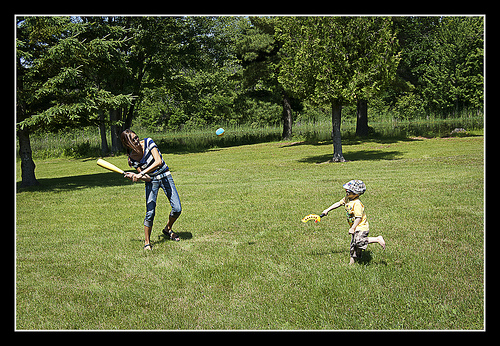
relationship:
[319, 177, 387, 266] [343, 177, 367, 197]
kid wearing hat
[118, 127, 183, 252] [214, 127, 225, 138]
woman hitting ball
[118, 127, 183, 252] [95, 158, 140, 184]
woman holding bat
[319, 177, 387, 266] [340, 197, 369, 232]
kid wearing shirt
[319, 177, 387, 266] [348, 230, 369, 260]
kid wearing shorts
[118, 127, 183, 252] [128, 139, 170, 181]
woman wearing shirt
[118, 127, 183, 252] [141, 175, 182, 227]
woman wearing jeans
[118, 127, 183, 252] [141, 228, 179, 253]
woman wearing sandals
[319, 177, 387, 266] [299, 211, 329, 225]
kid holding scoop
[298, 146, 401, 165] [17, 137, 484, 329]
shadow on grass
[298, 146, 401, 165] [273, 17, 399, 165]
shadow of tree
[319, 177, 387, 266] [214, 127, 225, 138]
kid pitching ball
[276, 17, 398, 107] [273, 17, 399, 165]
leaves on tree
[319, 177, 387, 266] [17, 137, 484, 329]
kid in grass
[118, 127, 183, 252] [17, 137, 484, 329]
woman in grass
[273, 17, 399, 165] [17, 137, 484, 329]
tree in grass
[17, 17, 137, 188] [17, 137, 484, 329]
tree in grass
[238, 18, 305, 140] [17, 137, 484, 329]
tree in grass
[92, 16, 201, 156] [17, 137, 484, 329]
tree in grass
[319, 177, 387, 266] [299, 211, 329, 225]
kid playing with scoop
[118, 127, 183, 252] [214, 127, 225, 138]
woman swinging at ball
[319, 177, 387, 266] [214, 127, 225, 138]
kid throwing ball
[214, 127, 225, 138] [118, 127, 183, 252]
ball thrown to woman